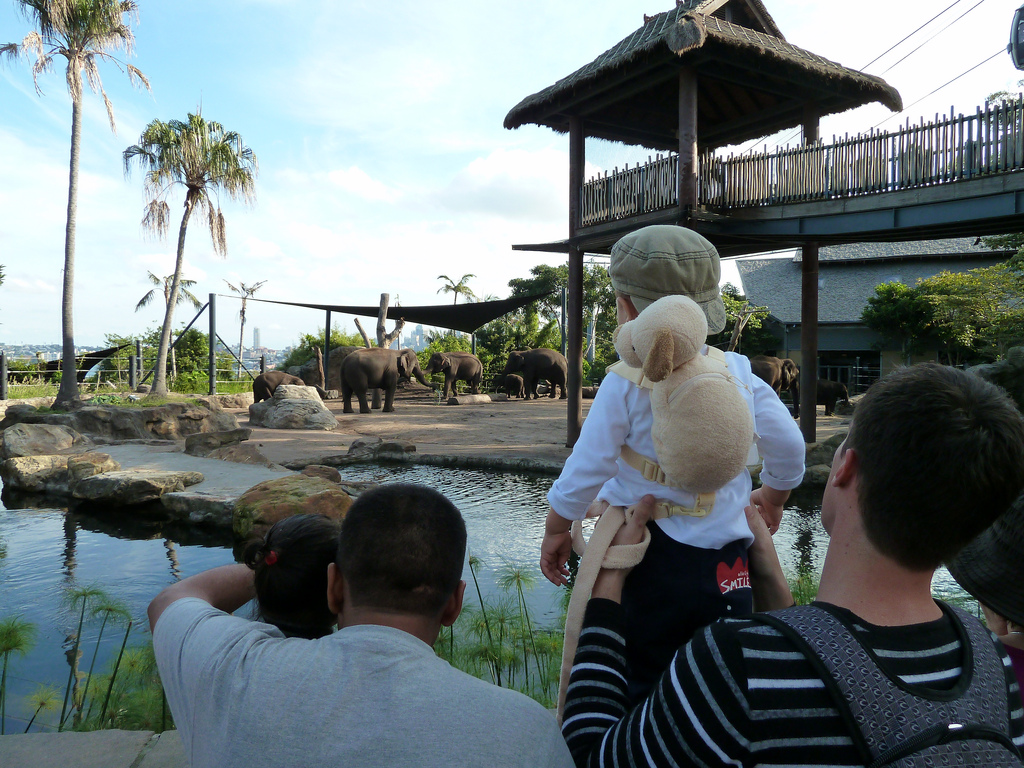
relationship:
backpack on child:
[585, 305, 764, 506] [536, 222, 816, 688]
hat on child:
[607, 221, 738, 333] [536, 222, 816, 688]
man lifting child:
[533, 370, 1009, 764] [536, 222, 816, 688]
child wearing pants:
[224, 497, 345, 659] [597, 510, 771, 735]